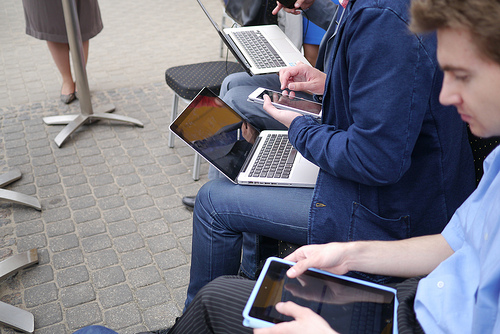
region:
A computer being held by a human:
[248, 258, 398, 333]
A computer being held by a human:
[159, 125, 314, 183]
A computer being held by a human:
[240, 78, 315, 123]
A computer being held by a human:
[188, 8, 310, 68]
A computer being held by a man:
[176, 2, 311, 66]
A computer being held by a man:
[172, 112, 325, 183]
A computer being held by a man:
[243, 78, 320, 133]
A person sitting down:
[192, 182, 497, 325]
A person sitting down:
[205, 108, 497, 243]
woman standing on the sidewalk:
[21, 4, 119, 106]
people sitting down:
[162, 2, 498, 332]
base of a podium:
[35, 98, 147, 148]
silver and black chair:
[154, 50, 264, 190]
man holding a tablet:
[129, 1, 499, 333]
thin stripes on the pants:
[154, 273, 251, 332]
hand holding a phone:
[239, 63, 335, 138]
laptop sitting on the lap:
[147, 75, 339, 209]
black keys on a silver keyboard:
[228, 16, 313, 83]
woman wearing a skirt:
[19, 2, 110, 107]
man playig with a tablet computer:
[236, 243, 406, 333]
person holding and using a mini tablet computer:
[242, 73, 334, 138]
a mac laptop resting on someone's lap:
[169, 79, 329, 194]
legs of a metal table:
[32, 0, 153, 169]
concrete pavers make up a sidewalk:
[59, 165, 163, 292]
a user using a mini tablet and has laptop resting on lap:
[172, 50, 329, 192]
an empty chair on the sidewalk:
[186, 17, 246, 96]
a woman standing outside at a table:
[17, 0, 117, 101]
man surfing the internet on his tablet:
[228, 225, 406, 332]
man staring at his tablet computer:
[391, 3, 493, 146]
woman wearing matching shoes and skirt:
[18, 5, 117, 107]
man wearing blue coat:
[194, 10, 454, 255]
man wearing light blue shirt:
[214, 24, 499, 330]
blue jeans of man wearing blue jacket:
[181, 175, 318, 272]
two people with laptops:
[175, 4, 424, 248]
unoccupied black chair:
[160, 8, 285, 160]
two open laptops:
[174, 1, 321, 182]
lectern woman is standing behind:
[20, 6, 142, 161]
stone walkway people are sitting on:
[14, 6, 299, 333]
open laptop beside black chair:
[197, 4, 305, 78]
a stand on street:
[35, 0, 145, 147]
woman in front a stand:
[15, 0, 145, 145]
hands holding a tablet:
[234, 230, 401, 332]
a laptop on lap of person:
[168, 66, 397, 231]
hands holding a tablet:
[239, 51, 347, 153]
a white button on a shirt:
[414, 167, 497, 329]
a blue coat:
[283, 2, 460, 238]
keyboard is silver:
[239, 123, 321, 197]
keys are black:
[243, 130, 303, 185]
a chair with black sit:
[161, 49, 245, 179]